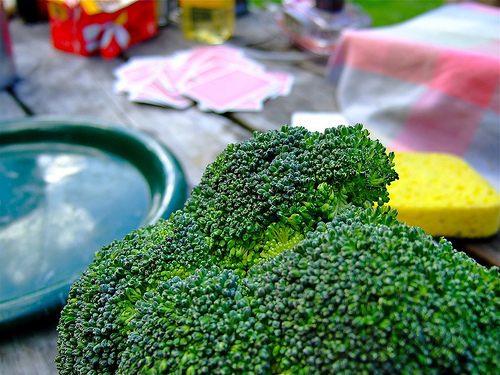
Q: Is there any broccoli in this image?
A: Yes, there is broccoli.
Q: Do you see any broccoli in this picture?
A: Yes, there is broccoli.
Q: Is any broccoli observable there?
A: Yes, there is broccoli.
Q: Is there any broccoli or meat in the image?
A: Yes, there is broccoli.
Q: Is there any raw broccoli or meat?
A: Yes, there is raw broccoli.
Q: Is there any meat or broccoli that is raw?
A: Yes, the broccoli is raw.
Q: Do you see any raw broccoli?
A: Yes, there is raw broccoli.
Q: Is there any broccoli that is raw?
A: Yes, there is broccoli that is raw.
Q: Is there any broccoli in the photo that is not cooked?
A: Yes, there is raw broccoli.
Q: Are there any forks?
A: No, there are no forks.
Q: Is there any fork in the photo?
A: No, there are no forks.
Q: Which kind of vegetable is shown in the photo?
A: The vegetable is broccoli.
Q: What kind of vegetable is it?
A: The vegetable is broccoli.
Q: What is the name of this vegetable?
A: That is broccoli.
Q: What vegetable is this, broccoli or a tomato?
A: That is broccoli.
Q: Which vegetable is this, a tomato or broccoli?
A: That is broccoli.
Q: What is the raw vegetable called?
A: The vegetable is broccoli.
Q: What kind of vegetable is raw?
A: The vegetable is broccoli.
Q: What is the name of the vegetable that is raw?
A: The vegetable is broccoli.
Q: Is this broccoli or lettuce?
A: This is broccoli.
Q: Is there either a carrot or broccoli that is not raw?
A: No, there is broccoli but it is raw.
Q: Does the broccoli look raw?
A: Yes, the broccoli is raw.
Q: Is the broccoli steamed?
A: No, the broccoli is raw.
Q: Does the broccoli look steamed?
A: No, the broccoli is raw.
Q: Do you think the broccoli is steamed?
A: No, the broccoli is raw.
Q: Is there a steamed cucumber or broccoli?
A: No, there is broccoli but it is raw.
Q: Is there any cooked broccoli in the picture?
A: No, there is broccoli but it is raw.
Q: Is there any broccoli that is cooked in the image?
A: No, there is broccoli but it is raw.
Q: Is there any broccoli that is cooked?
A: No, there is broccoli but it is raw.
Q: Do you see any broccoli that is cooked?
A: No, there is broccoli but it is raw.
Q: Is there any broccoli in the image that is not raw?
A: No, there is broccoli but it is raw.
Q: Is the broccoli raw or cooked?
A: The broccoli is raw.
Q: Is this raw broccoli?
A: Yes, this is raw broccoli.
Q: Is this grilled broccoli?
A: No, this is raw broccoli.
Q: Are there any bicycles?
A: No, there are no bicycles.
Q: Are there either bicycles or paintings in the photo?
A: No, there are no bicycles or paintings.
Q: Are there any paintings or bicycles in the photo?
A: No, there are no bicycles or paintings.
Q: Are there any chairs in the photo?
A: No, there are no chairs.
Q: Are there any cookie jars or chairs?
A: No, there are no chairs or cookie jars.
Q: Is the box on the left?
A: Yes, the box is on the left of the image.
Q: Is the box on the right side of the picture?
A: No, the box is on the left of the image.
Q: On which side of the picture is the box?
A: The box is on the left of the image.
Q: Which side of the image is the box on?
A: The box is on the left of the image.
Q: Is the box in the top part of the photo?
A: Yes, the box is in the top of the image.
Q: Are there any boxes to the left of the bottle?
A: Yes, there is a box to the left of the bottle.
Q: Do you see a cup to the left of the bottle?
A: No, there is a box to the left of the bottle.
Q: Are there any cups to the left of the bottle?
A: No, there is a box to the left of the bottle.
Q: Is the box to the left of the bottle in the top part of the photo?
A: Yes, the box is to the left of the bottle.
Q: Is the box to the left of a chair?
A: No, the box is to the left of the bottle.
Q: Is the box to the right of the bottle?
A: No, the box is to the left of the bottle.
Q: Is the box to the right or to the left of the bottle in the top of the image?
A: The box is to the left of the bottle.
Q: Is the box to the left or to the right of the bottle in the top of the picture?
A: The box is to the left of the bottle.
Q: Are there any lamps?
A: No, there are no lamps.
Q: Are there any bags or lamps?
A: No, there are no lamps or bags.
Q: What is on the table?
A: The cards are on the table.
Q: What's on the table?
A: The cards are on the table.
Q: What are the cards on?
A: The cards are on the table.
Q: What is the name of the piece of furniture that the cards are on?
A: The piece of furniture is a table.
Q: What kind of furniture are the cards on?
A: The cards are on the table.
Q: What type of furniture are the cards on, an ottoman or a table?
A: The cards are on a table.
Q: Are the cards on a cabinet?
A: No, the cards are on a table.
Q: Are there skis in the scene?
A: No, there are no skis.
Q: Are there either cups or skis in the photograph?
A: No, there are no skis or cups.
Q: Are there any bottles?
A: Yes, there is a bottle.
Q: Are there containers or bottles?
A: Yes, there is a bottle.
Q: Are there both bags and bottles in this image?
A: No, there is a bottle but no bags.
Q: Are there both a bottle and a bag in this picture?
A: No, there is a bottle but no bags.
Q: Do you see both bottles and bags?
A: No, there is a bottle but no bags.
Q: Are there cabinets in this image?
A: No, there are no cabinets.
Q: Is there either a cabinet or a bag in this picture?
A: No, there are no cabinets or bags.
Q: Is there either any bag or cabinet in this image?
A: No, there are no cabinets or bags.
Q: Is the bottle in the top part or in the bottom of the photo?
A: The bottle is in the top of the image.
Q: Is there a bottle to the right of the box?
A: Yes, there is a bottle to the right of the box.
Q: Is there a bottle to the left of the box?
A: No, the bottle is to the right of the box.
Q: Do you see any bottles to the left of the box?
A: No, the bottle is to the right of the box.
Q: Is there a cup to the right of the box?
A: No, there is a bottle to the right of the box.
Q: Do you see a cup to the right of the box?
A: No, there is a bottle to the right of the box.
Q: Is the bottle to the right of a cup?
A: No, the bottle is to the right of the box.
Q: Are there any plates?
A: Yes, there is a plate.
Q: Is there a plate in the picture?
A: Yes, there is a plate.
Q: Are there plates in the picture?
A: Yes, there is a plate.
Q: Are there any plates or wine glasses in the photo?
A: Yes, there is a plate.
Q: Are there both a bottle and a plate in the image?
A: Yes, there are both a plate and a bottle.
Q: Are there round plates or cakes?
A: Yes, there is a round plate.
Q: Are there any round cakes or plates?
A: Yes, there is a round plate.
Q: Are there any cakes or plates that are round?
A: Yes, the plate is round.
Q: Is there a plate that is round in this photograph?
A: Yes, there is a round plate.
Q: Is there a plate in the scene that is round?
A: Yes, there is a plate that is round.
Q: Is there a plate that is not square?
A: Yes, there is a round plate.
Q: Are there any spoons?
A: No, there are no spoons.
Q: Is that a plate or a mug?
A: That is a plate.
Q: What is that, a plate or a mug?
A: That is a plate.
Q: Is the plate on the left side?
A: Yes, the plate is on the left of the image.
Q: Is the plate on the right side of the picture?
A: No, the plate is on the left of the image.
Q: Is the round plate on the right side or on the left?
A: The plate is on the left of the image.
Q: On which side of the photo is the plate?
A: The plate is on the left of the image.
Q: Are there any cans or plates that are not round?
A: No, there is a plate but it is round.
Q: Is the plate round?
A: Yes, the plate is round.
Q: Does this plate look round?
A: Yes, the plate is round.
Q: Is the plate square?
A: No, the plate is round.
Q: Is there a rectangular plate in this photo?
A: No, there is a plate but it is round.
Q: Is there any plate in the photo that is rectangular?
A: No, there is a plate but it is round.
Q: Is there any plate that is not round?
A: No, there is a plate but it is round.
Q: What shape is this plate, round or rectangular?
A: The plate is round.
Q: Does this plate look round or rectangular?
A: The plate is round.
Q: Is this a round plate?
A: Yes, this is a round plate.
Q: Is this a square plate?
A: No, this is a round plate.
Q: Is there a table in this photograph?
A: Yes, there is a table.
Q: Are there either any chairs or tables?
A: Yes, there is a table.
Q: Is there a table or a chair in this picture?
A: Yes, there is a table.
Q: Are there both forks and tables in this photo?
A: No, there is a table but no forks.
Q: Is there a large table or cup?
A: Yes, there is a large table.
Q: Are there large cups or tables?
A: Yes, there is a large table.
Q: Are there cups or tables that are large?
A: Yes, the table is large.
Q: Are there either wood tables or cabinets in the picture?
A: Yes, there is a wood table.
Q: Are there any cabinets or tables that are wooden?
A: Yes, the table is wooden.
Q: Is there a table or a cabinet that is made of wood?
A: Yes, the table is made of wood.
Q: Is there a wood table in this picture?
A: Yes, there is a wood table.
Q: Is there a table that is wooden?
A: Yes, there is a table that is wooden.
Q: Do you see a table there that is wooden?
A: Yes, there is a table that is wooden.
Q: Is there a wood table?
A: Yes, there is a table that is made of wood.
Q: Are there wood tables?
A: Yes, there is a table that is made of wood.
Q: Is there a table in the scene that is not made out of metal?
A: Yes, there is a table that is made of wood.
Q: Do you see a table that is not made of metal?
A: Yes, there is a table that is made of wood.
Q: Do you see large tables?
A: Yes, there is a large table.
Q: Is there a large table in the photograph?
A: Yes, there is a large table.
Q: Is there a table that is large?
A: Yes, there is a table that is large.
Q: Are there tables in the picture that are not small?
A: Yes, there is a large table.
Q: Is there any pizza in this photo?
A: No, there are no pizzas.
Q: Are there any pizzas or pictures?
A: No, there are no pizzas or pictures.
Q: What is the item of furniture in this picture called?
A: The piece of furniture is a table.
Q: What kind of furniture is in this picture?
A: The furniture is a table.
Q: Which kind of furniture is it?
A: The piece of furniture is a table.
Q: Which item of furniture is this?
A: This is a table.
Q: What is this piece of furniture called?
A: This is a table.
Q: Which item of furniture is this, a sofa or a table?
A: This is a table.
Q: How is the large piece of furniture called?
A: The piece of furniture is a table.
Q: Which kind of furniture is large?
A: The furniture is a table.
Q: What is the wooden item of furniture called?
A: The piece of furniture is a table.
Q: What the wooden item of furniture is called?
A: The piece of furniture is a table.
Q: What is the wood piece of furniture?
A: The piece of furniture is a table.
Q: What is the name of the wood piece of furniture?
A: The piece of furniture is a table.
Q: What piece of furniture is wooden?
A: The piece of furniture is a table.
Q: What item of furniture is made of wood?
A: The piece of furniture is a table.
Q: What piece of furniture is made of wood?
A: The piece of furniture is a table.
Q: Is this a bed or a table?
A: This is a table.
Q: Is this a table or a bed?
A: This is a table.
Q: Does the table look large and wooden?
A: Yes, the table is large and wooden.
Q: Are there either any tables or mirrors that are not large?
A: No, there is a table but it is large.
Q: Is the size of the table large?
A: Yes, the table is large.